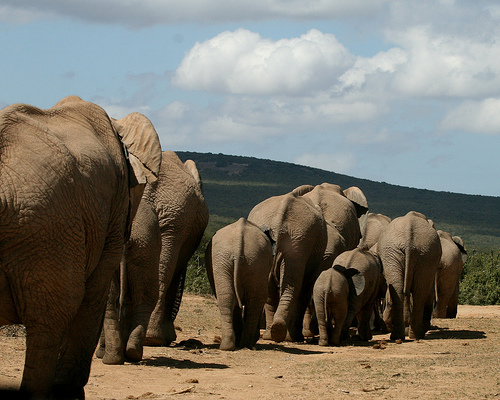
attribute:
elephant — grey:
[376, 201, 447, 351]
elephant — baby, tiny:
[310, 267, 355, 351]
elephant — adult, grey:
[3, 87, 166, 396]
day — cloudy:
[2, 3, 499, 157]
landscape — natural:
[7, 95, 498, 399]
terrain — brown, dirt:
[4, 281, 499, 400]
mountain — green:
[177, 147, 499, 231]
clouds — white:
[161, 23, 494, 130]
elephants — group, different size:
[4, 88, 471, 400]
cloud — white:
[158, 17, 365, 106]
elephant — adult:
[106, 136, 212, 367]